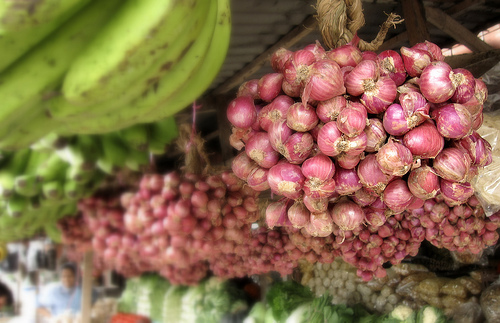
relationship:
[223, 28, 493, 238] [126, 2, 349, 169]
onions hanging from ceiling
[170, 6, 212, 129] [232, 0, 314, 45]
bananas hanging from ceiling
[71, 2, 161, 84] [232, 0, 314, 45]
bananas hanging from ceiling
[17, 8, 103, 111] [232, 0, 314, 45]
bananas hanging from ceiling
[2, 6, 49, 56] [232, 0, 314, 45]
bananas hanging from ceiling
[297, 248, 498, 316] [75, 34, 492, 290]
wood underneath onions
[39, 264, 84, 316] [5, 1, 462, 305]
man by stand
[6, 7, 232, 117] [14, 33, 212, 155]
collection of bananas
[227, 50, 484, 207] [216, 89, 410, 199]
ball of onions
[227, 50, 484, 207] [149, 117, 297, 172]
ball hanging by rope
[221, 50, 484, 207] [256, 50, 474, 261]
ball of onions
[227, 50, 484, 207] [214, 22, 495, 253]
ball of onions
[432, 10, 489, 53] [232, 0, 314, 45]
support beam on ceiling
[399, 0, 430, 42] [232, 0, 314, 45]
support beam on ceiling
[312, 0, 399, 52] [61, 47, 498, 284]
rope holding onions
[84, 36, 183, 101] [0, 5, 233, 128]
spots on bananas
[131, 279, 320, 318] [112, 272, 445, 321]
bags of celery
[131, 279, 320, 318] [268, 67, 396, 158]
bags under onions